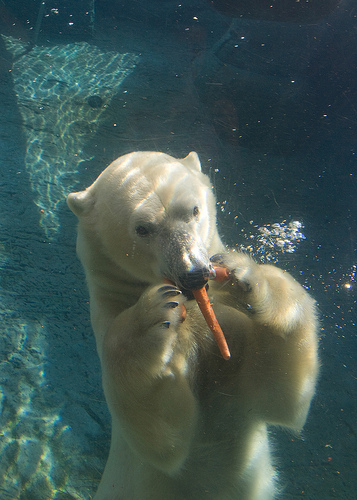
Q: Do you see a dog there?
A: No, there are no dogs.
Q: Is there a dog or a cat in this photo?
A: No, there are no dogs or cats.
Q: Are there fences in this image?
A: No, there are no fences.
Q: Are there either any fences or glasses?
A: No, there are no fences or glasses.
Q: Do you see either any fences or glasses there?
A: No, there are no fences or glasses.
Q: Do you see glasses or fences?
A: No, there are no fences or glasses.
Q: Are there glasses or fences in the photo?
A: No, there are no fences or glasses.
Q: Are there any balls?
A: No, there are no balls.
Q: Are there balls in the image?
A: No, there are no balls.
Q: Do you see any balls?
A: No, there are no balls.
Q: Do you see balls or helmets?
A: No, there are no balls or helmets.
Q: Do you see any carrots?
A: Yes, there is a carrot.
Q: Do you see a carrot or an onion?
A: Yes, there is a carrot.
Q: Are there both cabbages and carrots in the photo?
A: No, there is a carrot but no cabbages.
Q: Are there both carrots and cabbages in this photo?
A: No, there is a carrot but no cabbages.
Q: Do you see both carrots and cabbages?
A: No, there is a carrot but no cabbages.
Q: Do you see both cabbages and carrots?
A: No, there is a carrot but no cabbages.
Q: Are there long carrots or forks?
A: Yes, there is a long carrot.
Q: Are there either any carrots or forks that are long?
A: Yes, the carrot is long.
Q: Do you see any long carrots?
A: Yes, there is a long carrot.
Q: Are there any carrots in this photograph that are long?
A: Yes, there is a long carrot.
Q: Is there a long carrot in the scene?
A: Yes, there is a long carrot.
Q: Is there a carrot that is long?
A: Yes, there is a carrot that is long.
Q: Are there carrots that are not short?
A: Yes, there is a long carrot.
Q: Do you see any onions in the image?
A: No, there are no onions.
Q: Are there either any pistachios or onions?
A: No, there are no onions or pistachios.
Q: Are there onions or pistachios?
A: No, there are no onions or pistachios.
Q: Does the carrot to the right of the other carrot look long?
A: Yes, the carrot is long.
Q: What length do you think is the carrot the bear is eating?
A: The carrot is long.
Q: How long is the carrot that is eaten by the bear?
A: The carrot is long.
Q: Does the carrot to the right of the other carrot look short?
A: No, the carrot is long.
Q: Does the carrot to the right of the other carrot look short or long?
A: The carrot is long.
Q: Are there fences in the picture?
A: No, there are no fences.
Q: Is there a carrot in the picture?
A: Yes, there is a carrot.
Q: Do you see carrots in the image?
A: Yes, there is a carrot.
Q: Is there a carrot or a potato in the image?
A: Yes, there is a carrot.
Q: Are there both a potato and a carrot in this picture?
A: No, there is a carrot but no potatoes.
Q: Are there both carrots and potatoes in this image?
A: No, there is a carrot but no potatoes.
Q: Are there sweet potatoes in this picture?
A: No, there are no sweet potatoes.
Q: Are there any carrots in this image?
A: Yes, there is a carrot.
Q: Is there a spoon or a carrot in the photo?
A: Yes, there is a carrot.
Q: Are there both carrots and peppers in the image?
A: No, there is a carrot but no peppers.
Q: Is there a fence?
A: No, there are no fences.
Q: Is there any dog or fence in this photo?
A: No, there are no fences or dogs.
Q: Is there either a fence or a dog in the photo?
A: No, there are no fences or dogs.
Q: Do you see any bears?
A: Yes, there is a bear.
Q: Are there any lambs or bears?
A: Yes, there is a bear.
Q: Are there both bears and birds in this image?
A: No, there is a bear but no birds.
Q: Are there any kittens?
A: No, there are no kittens.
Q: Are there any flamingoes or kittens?
A: No, there are no kittens or flamingoes.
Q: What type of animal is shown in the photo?
A: The animal is a bear.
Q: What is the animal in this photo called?
A: The animal is a bear.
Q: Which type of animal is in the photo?
A: The animal is a bear.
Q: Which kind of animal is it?
A: The animal is a bear.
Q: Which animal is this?
A: This is a bear.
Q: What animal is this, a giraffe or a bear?
A: This is a bear.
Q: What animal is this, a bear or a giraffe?
A: This is a bear.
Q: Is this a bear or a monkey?
A: This is a bear.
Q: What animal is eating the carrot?
A: The bear is eating the carrot.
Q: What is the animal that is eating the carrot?
A: The animal is a bear.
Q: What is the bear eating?
A: The bear is eating a carrot.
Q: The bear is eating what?
A: The bear is eating a carrot.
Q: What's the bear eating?
A: The bear is eating a carrot.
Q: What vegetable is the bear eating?
A: The bear is eating a carrot.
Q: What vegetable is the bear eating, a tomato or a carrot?
A: The bear is eating a carrot.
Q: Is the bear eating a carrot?
A: Yes, the bear is eating a carrot.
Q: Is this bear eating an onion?
A: No, the bear is eating a carrot.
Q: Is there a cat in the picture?
A: No, there are no cats.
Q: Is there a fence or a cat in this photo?
A: No, there are no cats or fences.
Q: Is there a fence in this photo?
A: No, there are no fences.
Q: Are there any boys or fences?
A: No, there are no fences or boys.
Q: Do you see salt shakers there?
A: No, there are no salt shakers.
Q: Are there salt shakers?
A: No, there are no salt shakers.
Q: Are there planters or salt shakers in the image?
A: No, there are no salt shakers or planters.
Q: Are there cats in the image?
A: No, there are no cats.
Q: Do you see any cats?
A: No, there are no cats.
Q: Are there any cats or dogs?
A: No, there are no cats or dogs.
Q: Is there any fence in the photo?
A: No, there are no fences.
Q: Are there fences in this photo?
A: No, there are no fences.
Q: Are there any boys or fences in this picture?
A: No, there are no fences or boys.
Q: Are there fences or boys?
A: No, there are no fences or boys.